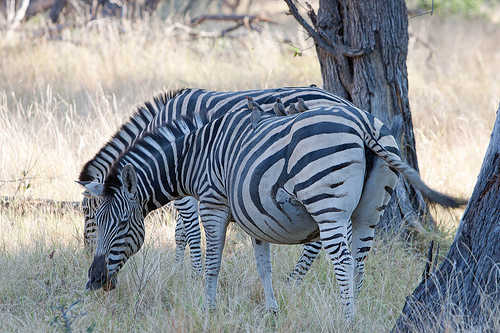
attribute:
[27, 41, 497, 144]
grass — yellow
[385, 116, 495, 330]
tree trunk — gray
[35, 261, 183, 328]
grass — yellow